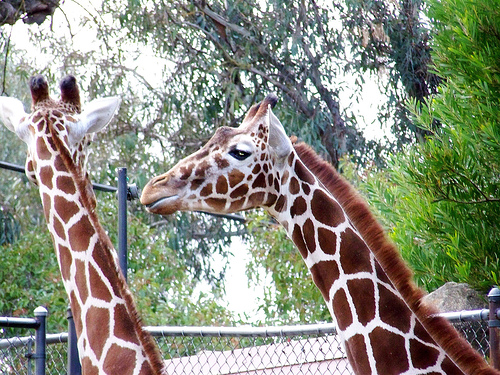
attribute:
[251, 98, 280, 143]
ear — white 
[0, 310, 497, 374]
fence — chain link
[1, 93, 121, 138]
ears — stuck out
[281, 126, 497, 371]
mane — red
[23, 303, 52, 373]
fence support — vertical, chain link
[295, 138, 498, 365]
mane — short, bristly, brown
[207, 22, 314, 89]
branches — grey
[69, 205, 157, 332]
mane — red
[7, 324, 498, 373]
fence — chain link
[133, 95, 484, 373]
giraffe — tall, white, brown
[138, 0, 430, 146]
tree branches — some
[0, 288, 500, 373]
fence — chain link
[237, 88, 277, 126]
horns — small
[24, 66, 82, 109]
horns — small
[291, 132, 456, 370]
mane — brown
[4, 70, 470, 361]
compound — zoo